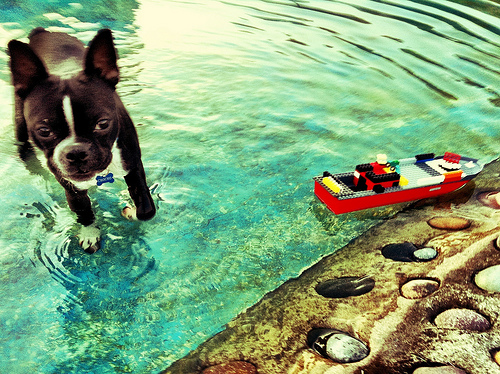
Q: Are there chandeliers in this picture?
A: No, there are no chandeliers.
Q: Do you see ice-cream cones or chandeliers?
A: No, there are no chandeliers or ice-cream cones.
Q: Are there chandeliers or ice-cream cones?
A: No, there are no chandeliers or ice-cream cones.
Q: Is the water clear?
A: Yes, the water is clear.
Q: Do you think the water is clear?
A: Yes, the water is clear.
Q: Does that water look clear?
A: Yes, the water is clear.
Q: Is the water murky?
A: No, the water is clear.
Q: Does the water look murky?
A: No, the water is clear.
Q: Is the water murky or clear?
A: The water is clear.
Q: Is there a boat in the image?
A: Yes, there is a boat.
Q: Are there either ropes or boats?
A: Yes, there is a boat.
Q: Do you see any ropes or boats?
A: Yes, there is a boat.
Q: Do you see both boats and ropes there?
A: No, there is a boat but no ropes.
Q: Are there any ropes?
A: No, there are no ropes.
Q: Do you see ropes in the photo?
A: No, there are no ropes.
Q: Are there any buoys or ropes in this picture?
A: No, there are no ropes or buoys.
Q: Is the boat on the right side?
A: Yes, the boat is on the right of the image.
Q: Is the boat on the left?
A: No, the boat is on the right of the image.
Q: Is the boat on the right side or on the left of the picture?
A: The boat is on the right of the image.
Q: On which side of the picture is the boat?
A: The boat is on the right of the image.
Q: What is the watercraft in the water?
A: The watercraft is a boat.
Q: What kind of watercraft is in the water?
A: The watercraft is a boat.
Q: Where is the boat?
A: The boat is in the water.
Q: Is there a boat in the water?
A: Yes, there is a boat in the water.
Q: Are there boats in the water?
A: Yes, there is a boat in the water.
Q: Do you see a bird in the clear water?
A: No, there is a boat in the water.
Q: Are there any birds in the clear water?
A: No, there is a boat in the water.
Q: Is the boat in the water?
A: Yes, the boat is in the water.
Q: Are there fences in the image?
A: No, there are no fences.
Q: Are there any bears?
A: No, there are no bears.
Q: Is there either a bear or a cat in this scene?
A: No, there are no bears or cats.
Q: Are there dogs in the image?
A: Yes, there is a dog.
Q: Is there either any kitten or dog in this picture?
A: Yes, there is a dog.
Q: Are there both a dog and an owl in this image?
A: No, there is a dog but no owls.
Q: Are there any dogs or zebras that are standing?
A: Yes, the dog is standing.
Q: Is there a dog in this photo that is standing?
A: Yes, there is a dog that is standing.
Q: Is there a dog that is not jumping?
A: Yes, there is a dog that is standing.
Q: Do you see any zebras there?
A: No, there are no zebras.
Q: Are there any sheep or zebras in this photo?
A: No, there are no zebras or sheep.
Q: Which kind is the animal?
A: The animal is a dog.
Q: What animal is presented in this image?
A: The animal is a dog.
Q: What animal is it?
A: The animal is a dog.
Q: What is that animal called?
A: This is a dog.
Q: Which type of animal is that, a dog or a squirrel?
A: This is a dog.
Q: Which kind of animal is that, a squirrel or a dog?
A: This is a dog.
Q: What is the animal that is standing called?
A: The animal is a dog.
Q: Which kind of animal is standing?
A: The animal is a dog.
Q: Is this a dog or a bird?
A: This is a dog.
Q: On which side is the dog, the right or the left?
A: The dog is on the left of the image.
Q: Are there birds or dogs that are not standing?
A: No, there is a dog but it is standing.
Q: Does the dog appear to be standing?
A: Yes, the dog is standing.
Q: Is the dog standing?
A: Yes, the dog is standing.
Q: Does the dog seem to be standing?
A: Yes, the dog is standing.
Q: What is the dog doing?
A: The dog is standing.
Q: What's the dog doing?
A: The dog is standing.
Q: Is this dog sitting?
A: No, the dog is standing.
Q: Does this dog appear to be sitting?
A: No, the dog is standing.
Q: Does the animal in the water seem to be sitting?
A: No, the dog is standing.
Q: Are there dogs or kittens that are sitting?
A: No, there is a dog but it is standing.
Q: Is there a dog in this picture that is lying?
A: No, there is a dog but it is standing.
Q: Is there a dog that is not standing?
A: No, there is a dog but it is standing.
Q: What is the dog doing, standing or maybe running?
A: The dog is standing.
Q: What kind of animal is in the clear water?
A: The animal is a dog.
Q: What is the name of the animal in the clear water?
A: The animal is a dog.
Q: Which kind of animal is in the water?
A: The animal is a dog.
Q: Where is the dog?
A: The dog is in the water.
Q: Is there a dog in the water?
A: Yes, there is a dog in the water.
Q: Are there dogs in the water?
A: Yes, there is a dog in the water.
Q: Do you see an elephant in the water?
A: No, there is a dog in the water.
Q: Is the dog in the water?
A: Yes, the dog is in the water.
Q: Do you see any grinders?
A: No, there are no grinders.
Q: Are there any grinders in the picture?
A: No, there are no grinders.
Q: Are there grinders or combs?
A: No, there are no grinders or combs.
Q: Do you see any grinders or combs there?
A: No, there are no grinders or combs.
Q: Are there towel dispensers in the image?
A: No, there are no towel dispensers.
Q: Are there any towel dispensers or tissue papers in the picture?
A: No, there are no towel dispensers or tissue papers.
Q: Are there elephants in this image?
A: No, there are no elephants.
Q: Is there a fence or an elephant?
A: No, there are no elephants or fences.